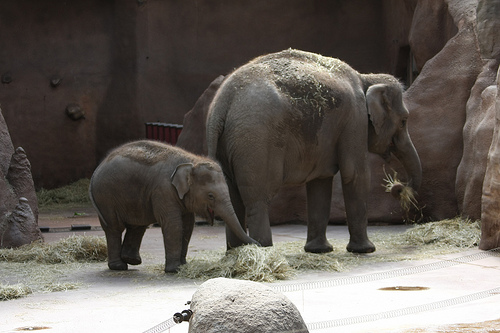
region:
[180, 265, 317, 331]
Medium-sized rounded rock in the foreground of the picture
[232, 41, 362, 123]
Grass on the elephant's back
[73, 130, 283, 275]
Baby elephant next to a larger elephant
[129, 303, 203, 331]
Spring attached to a rock by a black plastic piece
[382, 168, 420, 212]
Hay and grass in the elephant's trunk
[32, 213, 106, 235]
Spring with black parts on the ground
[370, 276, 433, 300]
Circular pile of mud on the ground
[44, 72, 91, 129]
Objects poking out of the wall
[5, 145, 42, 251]
Two towers of rock next to the elephants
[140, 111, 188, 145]
Bars behind the elephant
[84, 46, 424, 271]
Two gray elephants in an exhibit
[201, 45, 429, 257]
Large grey elephant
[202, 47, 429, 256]
Large grey elephant eating hay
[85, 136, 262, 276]
Small grey elephant eating hay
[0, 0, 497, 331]
Rocky elephant exhibit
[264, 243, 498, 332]
Two ropes of spiral wire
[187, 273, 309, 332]
large grey rock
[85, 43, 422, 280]
Large and small elephant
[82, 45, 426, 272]
Two elephants eating hay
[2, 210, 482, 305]
Piles of hay on the ground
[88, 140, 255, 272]
A baby elephants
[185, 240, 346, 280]
A pile of food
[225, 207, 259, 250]
A baby elephant's trunk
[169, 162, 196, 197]
A baby elephant's ear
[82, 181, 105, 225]
An elephant's tail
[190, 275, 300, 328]
A small rock on the ground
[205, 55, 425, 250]
A larger elephant eating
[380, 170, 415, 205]
Food in an elephant's trunk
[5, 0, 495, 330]
Elephants in an enclosure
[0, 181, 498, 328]
Food scattered around the ground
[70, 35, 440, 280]
Two elephants near rocks.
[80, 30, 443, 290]
Two gray elephants standing near rocks.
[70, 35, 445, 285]
Two elephants facing to the right.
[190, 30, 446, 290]
An elephant picking up grass.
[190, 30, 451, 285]
A gray elephant standing and picking up grass.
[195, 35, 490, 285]
A pile of grass near an elephant.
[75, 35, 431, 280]
A bigger and shorter elephant.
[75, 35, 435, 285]
A taller and shorter elephant.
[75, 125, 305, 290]
A small elephant near a pile of grass.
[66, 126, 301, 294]
A small elephant standing next to a pile of grass.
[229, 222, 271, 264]
This elephant has a small trunk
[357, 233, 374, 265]
This elephant has a large foot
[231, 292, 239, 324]
There is a large rock here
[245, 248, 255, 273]
There is some straw visible here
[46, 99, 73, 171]
There is a terra cotta wall here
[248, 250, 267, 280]
There is straw that is visible here